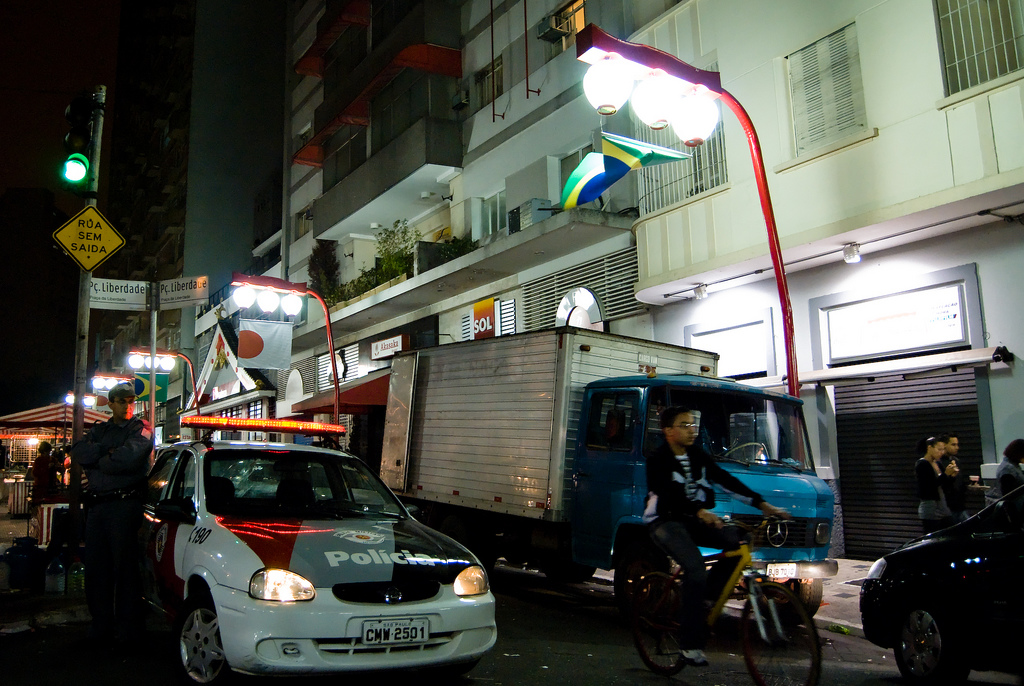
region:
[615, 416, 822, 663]
person is riding a bike down the street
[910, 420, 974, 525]
people are walking on the sidewalk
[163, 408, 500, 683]
police car in the street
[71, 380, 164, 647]
police officer standing by his car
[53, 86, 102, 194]
traffic light with green lit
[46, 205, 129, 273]
yellow sign in a foreign language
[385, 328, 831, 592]
blue truck parked on the side of the road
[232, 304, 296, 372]
flag on the side of the buidling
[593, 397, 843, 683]
A guy on a yellow bike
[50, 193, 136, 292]
A yellow sign hanging on a stoplight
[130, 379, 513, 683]
A white police vehicle with headlights on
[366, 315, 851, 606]
A large blue cargo truck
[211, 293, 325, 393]
A red and white flag hanging on a streetlight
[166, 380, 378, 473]
Orange police lights on police vehicle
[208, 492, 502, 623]
A red, gray, and black hood on a police vehicle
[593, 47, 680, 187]
white lights on pole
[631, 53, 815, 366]
red and arched pole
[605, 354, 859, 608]
blue truck is parked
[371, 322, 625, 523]
white trailer on truck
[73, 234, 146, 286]
black and yellow sign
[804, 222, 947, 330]
white light on building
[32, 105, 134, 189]
traffic light is green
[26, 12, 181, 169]
sky is pitch black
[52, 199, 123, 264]
the diamond shaped yellow and black sign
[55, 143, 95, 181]
the green bright light of the traffic light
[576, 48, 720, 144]
the bright round white lamps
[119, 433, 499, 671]
the black grey and white police car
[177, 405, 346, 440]
the bright orange light of the police car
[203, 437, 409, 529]
the windshield of the police car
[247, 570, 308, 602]
the bright headlight of the police car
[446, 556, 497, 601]
the bright headlight of the police car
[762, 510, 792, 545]
the silver emblem on the truck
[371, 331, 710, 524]
cargo container on truck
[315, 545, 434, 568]
the text is white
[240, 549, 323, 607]
part of a vehicle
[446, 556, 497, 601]
part of a vehicle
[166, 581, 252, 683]
part of a vehicle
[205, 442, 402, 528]
part of a vehicle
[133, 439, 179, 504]
part of a vehicle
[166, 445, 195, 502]
part of a vehicle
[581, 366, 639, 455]
part of a vehicle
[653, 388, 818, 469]
part of a vehicle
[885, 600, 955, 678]
part of a vehicle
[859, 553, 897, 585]
part of a vehicle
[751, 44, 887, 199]
a window on the building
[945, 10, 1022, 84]
a window on the building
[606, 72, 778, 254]
a window on the building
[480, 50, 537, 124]
a window on the building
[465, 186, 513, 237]
a window on the building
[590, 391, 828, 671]
man in a yellow bike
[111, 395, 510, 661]
white colored police car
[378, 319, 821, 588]
blue and white colored van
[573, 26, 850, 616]
red colored street light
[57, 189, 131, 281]
yellow colored street sign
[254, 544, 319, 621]
headlight of the police car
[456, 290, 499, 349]
yellow colored sign on building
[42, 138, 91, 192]
green colored stop light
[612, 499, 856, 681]
yellow colored bike on road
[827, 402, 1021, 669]
black sedan parked on street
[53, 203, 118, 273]
yellow and black street sign